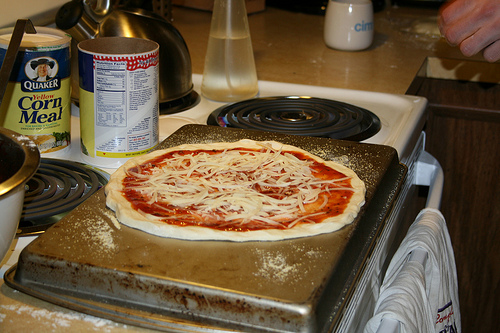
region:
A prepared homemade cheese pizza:
[101, 133, 370, 245]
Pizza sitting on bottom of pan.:
[98, 137, 368, 247]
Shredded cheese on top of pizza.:
[175, 154, 297, 211]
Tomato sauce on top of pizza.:
[324, 169, 351, 219]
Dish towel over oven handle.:
[370, 201, 459, 332]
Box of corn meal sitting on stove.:
[3, 18, 75, 157]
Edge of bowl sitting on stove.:
[0, 125, 41, 275]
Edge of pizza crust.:
[107, 212, 212, 237]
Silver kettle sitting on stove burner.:
[51, 0, 197, 107]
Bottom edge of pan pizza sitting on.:
[0, 240, 347, 330]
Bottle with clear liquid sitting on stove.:
[195, 5, 265, 100]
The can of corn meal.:
[5, 16, 74, 144]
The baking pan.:
[49, 113, 400, 330]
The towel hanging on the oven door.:
[370, 213, 485, 330]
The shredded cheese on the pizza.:
[130, 132, 335, 219]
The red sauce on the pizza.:
[123, 147, 345, 226]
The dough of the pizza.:
[105, 138, 364, 234]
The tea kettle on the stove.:
[61, 1, 198, 103]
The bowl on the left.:
[0, 125, 42, 265]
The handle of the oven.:
[357, 161, 439, 322]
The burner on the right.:
[209, 86, 376, 139]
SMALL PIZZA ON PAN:
[103, 134, 332, 249]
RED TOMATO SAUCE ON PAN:
[202, 183, 272, 238]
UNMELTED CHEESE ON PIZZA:
[214, 170, 279, 225]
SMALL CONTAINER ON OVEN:
[80, 26, 165, 156]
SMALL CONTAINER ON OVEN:
[0, 26, 67, 130]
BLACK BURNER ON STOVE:
[3, 147, 99, 229]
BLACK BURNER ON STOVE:
[220, 70, 381, 132]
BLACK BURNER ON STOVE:
[112, 89, 194, 124]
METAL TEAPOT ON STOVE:
[64, 6, 173, 101]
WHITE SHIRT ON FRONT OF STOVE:
[398, 244, 475, 329]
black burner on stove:
[236, 94, 342, 126]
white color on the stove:
[385, 95, 408, 125]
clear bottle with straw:
[196, 25, 276, 90]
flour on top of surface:
[79, 221, 116, 245]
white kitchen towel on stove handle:
[388, 254, 468, 324]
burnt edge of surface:
[130, 284, 203, 303]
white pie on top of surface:
[105, 138, 369, 241]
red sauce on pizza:
[136, 193, 169, 210]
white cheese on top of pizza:
[161, 176, 229, 203]